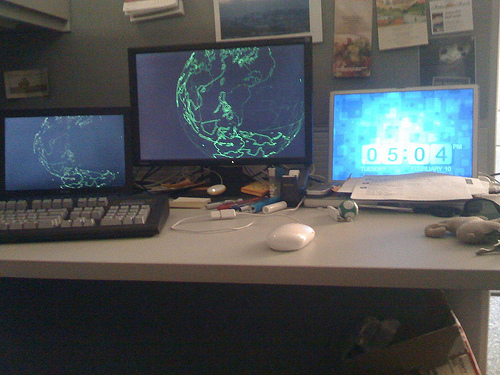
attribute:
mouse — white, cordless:
[262, 215, 321, 256]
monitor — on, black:
[3, 105, 145, 203]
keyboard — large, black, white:
[2, 186, 172, 246]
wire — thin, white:
[171, 201, 313, 234]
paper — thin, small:
[337, 163, 481, 212]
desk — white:
[3, 175, 497, 288]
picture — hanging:
[207, 1, 325, 48]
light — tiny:
[227, 159, 238, 166]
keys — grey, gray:
[3, 195, 154, 234]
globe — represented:
[28, 114, 121, 188]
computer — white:
[326, 84, 483, 194]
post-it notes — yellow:
[239, 174, 274, 199]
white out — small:
[207, 207, 242, 223]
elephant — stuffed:
[422, 210, 498, 252]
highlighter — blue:
[249, 190, 284, 220]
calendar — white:
[381, 7, 432, 53]